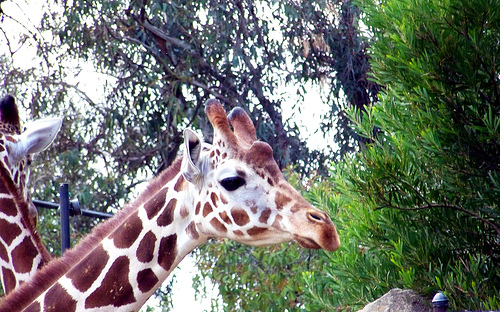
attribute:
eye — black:
[221, 175, 246, 191]